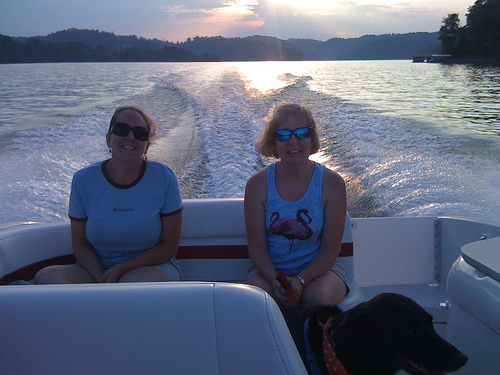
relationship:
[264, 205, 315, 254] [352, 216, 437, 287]
flamingos on door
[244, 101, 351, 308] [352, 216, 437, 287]
woman wearing door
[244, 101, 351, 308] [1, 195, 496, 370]
woman on boat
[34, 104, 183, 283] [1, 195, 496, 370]
ladies on boat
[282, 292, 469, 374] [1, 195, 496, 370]
dog on boat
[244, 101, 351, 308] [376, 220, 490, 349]
woman on boat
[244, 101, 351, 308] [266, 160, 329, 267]
woman beside tank top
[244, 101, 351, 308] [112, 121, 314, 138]
woman beside sunglasses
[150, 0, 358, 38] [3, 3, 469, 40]
light through clouds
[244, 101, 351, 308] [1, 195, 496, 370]
woman riding boat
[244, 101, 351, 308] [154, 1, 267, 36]
woman at sunset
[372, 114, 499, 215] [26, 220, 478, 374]
wake by boat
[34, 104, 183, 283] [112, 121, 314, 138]
ladies wears sunglasses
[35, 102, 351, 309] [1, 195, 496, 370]
two women on boat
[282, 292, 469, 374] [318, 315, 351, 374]
dog has handkerchief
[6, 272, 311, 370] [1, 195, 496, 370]
seat on boat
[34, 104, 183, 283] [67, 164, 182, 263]
ladies wears tshirt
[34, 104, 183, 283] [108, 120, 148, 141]
ladies wears sunglasses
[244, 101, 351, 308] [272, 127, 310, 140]
woman wears sunglasses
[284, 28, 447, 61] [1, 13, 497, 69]
mountain on background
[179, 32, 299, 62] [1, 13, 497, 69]
mountain on background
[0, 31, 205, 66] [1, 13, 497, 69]
mountain on background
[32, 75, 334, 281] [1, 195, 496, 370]
ladies on boat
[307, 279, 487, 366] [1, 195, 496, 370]
dog on boat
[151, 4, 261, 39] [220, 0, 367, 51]
sun behind clouds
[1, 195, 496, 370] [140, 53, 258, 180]
boat create wake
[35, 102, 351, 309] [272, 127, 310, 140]
two women wears sunglasses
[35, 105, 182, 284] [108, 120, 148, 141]
two women wears sunglasses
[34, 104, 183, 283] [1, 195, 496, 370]
ladies sitting on boat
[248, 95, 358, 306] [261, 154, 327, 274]
woman wearing flamingo shirt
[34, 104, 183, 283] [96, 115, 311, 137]
ladies wearing sunglasses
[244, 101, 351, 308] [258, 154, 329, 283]
woman wearing shirt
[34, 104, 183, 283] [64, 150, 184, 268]
ladies wearing shirt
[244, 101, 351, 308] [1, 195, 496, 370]
woman in back of boat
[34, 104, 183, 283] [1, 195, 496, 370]
ladies in back of boat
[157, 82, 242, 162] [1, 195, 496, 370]
wake behind boat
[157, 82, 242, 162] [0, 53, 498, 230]
wake in water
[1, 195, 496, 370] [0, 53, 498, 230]
boat in water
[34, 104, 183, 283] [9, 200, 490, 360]
ladies on boat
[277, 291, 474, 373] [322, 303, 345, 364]
black lab with handkerchief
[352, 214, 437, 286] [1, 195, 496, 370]
door on back of boat